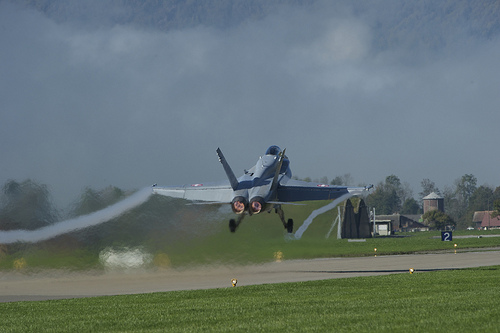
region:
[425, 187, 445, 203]
top lid of the silo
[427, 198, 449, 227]
base of the silo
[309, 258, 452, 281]
runway for the plane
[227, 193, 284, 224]
fuel burners of the plane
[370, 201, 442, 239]
farm sheds next to the silo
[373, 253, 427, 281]
airport lights for the runway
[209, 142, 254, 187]
Tail of the plne that is taking off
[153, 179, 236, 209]
left wing of the plane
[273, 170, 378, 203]
right wing of the plane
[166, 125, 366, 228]
plane taking off above the runway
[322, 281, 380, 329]
The grass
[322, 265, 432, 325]
The grass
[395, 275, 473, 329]
The grass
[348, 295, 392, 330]
The grass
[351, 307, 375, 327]
The grass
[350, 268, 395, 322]
The grass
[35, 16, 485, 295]
a jet fighter taking off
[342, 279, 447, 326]
green, well manicured grass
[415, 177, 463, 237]
a grain silo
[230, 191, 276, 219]
ignited jet engines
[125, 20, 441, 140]
low lying clouds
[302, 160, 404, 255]
a fighter jet wing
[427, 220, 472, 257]
a sign with the number 2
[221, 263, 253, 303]
a light marking the edge of the runway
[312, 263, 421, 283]
a flat paved surface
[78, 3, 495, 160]
foothills and clouds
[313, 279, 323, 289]
The grass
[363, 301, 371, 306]
The grass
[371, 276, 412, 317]
The grass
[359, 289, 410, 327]
The grass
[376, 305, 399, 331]
The grass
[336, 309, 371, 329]
The grass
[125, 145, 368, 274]
The plane is taking off.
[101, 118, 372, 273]
The plane is small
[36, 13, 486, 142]
It is stormy outside.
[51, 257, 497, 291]
The runway is clear.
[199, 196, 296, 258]
The jets are hot.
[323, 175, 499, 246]
The buildings are next to the run way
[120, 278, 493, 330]
The grass is growing.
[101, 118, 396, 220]
The plane is grey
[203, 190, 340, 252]
The wheels are down.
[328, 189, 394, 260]
The trees are trimmed.